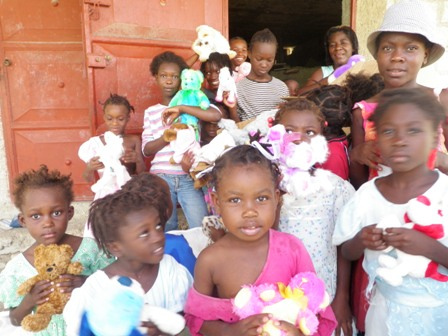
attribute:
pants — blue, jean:
[161, 166, 203, 230]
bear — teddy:
[12, 240, 85, 331]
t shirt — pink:
[184, 226, 339, 334]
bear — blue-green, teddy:
[167, 62, 223, 150]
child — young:
[136, 45, 225, 234]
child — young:
[239, 24, 286, 118]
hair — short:
[249, 24, 277, 44]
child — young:
[184, 129, 336, 329]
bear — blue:
[267, 294, 309, 321]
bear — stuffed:
[194, 243, 349, 328]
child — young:
[67, 88, 154, 184]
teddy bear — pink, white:
[231, 268, 334, 334]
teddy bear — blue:
[166, 67, 210, 141]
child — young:
[59, 193, 199, 335]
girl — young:
[182, 128, 338, 335]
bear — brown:
[18, 243, 80, 329]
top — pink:
[190, 233, 293, 334]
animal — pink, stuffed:
[232, 268, 326, 335]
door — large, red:
[0, 11, 238, 205]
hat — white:
[362, 1, 443, 56]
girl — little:
[266, 91, 353, 298]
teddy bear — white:
[282, 137, 349, 309]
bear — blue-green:
[168, 66, 209, 128]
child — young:
[238, 27, 295, 121]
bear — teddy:
[233, 268, 332, 333]